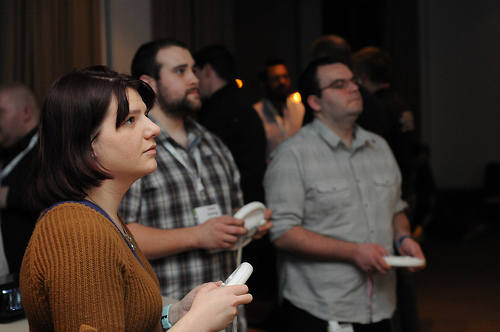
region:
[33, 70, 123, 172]
Person has dark hair.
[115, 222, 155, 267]
Woman wearing necklace around neck.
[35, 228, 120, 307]
Woman wearing brown sweater.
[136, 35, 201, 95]
Man has dark hair.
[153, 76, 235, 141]
Man has dark facial hair.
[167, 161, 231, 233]
Man wearing plaid shirt.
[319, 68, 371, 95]
Man wearing glasses on face.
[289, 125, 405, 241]
Man wearing button down shirt.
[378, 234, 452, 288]
Man holding remote control.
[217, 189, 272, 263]
Man holding remote control.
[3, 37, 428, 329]
people wit WII controllers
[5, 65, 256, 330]
woman in a brown sweater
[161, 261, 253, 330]
hands holding a WII cntroller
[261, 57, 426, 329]
a man wearing glasses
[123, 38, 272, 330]
man in a checkered shirt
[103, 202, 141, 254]
a necklace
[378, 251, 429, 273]
white WII controller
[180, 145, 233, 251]
name badge covered by a hand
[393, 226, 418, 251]
a watch on a wrist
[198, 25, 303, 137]
people in the back ground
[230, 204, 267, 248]
White steering wheel remote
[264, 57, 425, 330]
A middle aged man standing with a game controller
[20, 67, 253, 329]
A young lady standing holding a game remote controller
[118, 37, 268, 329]
A young man standing holding a remote game controller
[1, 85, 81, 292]
A seated man in black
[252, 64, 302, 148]
A onlooker in white watching the people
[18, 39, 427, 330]
A group of people playing a game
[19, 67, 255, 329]
A young lady in a brown shirt playing a video game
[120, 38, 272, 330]
A midle aged man with short black hair and a beard playing a video game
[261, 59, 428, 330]
A middle aged man with short black hair and glasses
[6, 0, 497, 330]
group of people indoors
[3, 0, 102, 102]
tan curtains on window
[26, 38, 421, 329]
three people with game controls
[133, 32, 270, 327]
man in plaid shirt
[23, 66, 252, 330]
woman with game control in hands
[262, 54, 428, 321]
man with open collar shirt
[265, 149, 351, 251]
rolled up sleeve on arm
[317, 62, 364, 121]
eye glasses on face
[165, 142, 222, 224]
tag on white ribbon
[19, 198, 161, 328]
sleeve of ribbed brown sweater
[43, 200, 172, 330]
the sweater is brown in color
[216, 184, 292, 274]
game controller is white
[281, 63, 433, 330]
the man has glasses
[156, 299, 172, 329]
the watch is on the wrist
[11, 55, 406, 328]
the people are playing game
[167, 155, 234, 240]
key tag is on the chest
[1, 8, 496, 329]
the guys are in indoors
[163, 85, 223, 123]
the chin has beard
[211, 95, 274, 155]
the suit is black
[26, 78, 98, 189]
the hair is brown